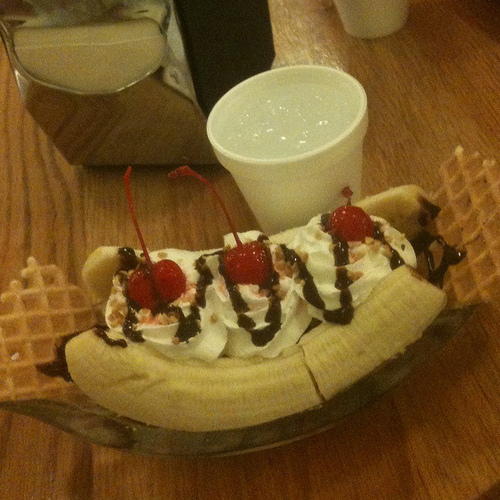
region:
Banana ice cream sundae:
[81, 211, 463, 441]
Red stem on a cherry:
[116, 170, 164, 270]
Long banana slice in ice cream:
[79, 278, 438, 401]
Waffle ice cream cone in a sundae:
[2, 258, 94, 401]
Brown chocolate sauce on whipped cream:
[295, 246, 367, 326]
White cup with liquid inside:
[209, 71, 379, 229]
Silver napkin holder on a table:
[2, 3, 209, 179]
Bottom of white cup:
[330, 2, 422, 41]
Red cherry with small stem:
[327, 187, 372, 239]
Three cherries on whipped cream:
[121, 192, 391, 309]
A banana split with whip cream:
[0, 143, 499, 456]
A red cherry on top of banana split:
[125, 162, 185, 311]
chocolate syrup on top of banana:
[277, 232, 363, 326]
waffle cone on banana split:
[1, 251, 101, 403]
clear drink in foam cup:
[207, 63, 374, 238]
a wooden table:
[379, 62, 479, 99]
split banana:
[64, 263, 449, 434]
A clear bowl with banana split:
[1, 301, 496, 460]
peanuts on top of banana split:
[105, 291, 127, 330]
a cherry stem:
[122, 163, 156, 264]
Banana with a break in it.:
[62, 330, 420, 410]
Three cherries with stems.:
[108, 195, 378, 308]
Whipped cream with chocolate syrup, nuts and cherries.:
[115, 197, 485, 368]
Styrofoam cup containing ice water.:
[204, 62, 377, 242]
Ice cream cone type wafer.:
[0, 254, 127, 414]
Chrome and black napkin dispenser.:
[0, 0, 287, 175]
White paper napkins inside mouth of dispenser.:
[5, 4, 185, 113]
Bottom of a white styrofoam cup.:
[327, 1, 433, 47]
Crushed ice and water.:
[239, 92, 326, 139]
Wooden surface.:
[386, 27, 468, 169]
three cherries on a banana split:
[68, 189, 435, 346]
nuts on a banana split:
[64, 218, 428, 344]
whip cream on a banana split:
[71, 195, 422, 357]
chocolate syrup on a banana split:
[46, 240, 448, 348]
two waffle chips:
[0, 130, 478, 395]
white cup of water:
[177, 64, 401, 216]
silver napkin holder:
[11, 23, 203, 167]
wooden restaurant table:
[3, 71, 482, 253]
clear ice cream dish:
[32, 304, 458, 449]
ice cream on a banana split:
[84, 190, 426, 362]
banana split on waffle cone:
[5, 149, 487, 451]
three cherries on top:
[121, 190, 371, 311]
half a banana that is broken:
[63, 261, 443, 426]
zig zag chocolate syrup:
[95, 210, 398, 351]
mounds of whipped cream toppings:
[105, 207, 407, 361]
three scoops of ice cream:
[100, 197, 402, 363]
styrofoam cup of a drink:
[195, 50, 372, 255]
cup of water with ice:
[201, 62, 372, 249]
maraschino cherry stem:
[121, 164, 149, 267]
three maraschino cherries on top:
[115, 181, 370, 303]